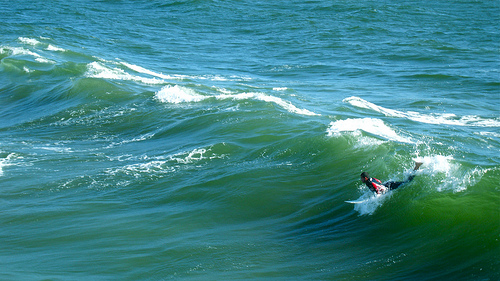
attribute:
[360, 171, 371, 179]
hair — short, black, dark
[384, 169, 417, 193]
pants — dark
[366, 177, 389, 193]
shirt — red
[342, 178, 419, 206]
surfboard — part, white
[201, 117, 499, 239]
wave — part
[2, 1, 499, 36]
water — distant, part, blue, green, calm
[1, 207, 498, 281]
water — part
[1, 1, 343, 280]
ocean water — green, beautiful, blue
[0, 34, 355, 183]
waves — choppy